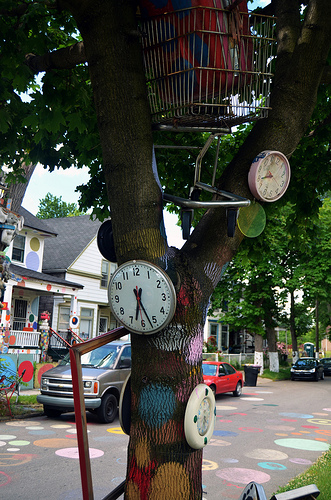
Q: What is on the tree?
A: Clocks.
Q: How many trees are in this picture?
A: One.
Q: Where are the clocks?
A: On the tree.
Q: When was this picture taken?
A: Daytime.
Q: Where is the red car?
A: Behind the tree.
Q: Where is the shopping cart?
A: On the tree.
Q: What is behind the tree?
A: The street.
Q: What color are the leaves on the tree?
A: Green.